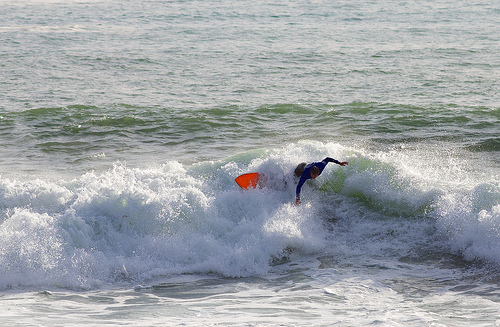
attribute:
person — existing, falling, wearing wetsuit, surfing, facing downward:
[285, 158, 352, 209]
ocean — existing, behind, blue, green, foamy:
[0, 1, 499, 326]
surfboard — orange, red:
[231, 170, 262, 192]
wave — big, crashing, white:
[0, 128, 498, 297]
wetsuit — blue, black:
[292, 157, 341, 199]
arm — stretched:
[292, 175, 309, 203]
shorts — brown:
[292, 161, 308, 178]